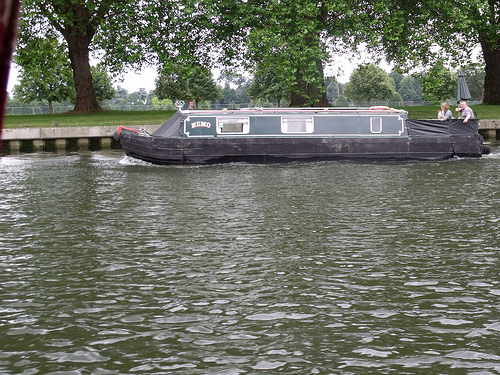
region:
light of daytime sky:
[10, 33, 484, 95]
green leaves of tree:
[345, 63, 391, 99]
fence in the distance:
[3, 101, 440, 115]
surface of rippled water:
[3, 144, 498, 372]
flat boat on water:
[115, 107, 491, 162]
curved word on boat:
[191, 120, 211, 130]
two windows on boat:
[215, 115, 314, 134]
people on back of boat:
[436, 100, 475, 125]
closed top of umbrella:
[453, 67, 470, 104]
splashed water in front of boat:
[119, 154, 154, 167]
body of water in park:
[15, 169, 490, 364]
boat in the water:
[106, 96, 491, 178]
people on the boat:
[426, 98, 478, 138]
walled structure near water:
[2, 122, 129, 146]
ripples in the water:
[353, 338, 480, 365]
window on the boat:
[218, 114, 250, 131]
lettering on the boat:
[187, 118, 214, 132]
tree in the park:
[338, 53, 403, 109]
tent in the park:
[443, 66, 476, 111]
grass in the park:
[21, 112, 152, 124]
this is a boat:
[113, 102, 438, 159]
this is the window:
[217, 119, 246, 134]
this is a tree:
[145, 14, 217, 100]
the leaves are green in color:
[174, 61, 192, 83]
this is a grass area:
[55, 110, 93, 125]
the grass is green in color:
[36, 106, 71, 123]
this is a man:
[455, 90, 480, 125]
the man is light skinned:
[458, 101, 467, 116]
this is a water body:
[149, 174, 430, 352]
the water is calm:
[282, 200, 468, 315]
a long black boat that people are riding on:
[113, 100, 490, 168]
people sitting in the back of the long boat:
[432, 94, 474, 121]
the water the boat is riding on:
[2, 149, 498, 373]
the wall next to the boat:
[4, 125, 116, 149]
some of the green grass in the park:
[10, 111, 169, 123]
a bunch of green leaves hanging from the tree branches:
[117, 4, 485, 108]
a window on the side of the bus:
[218, 118, 245, 133]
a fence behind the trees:
[4, 100, 79, 115]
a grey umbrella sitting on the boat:
[454, 70, 470, 100]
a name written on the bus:
[190, 120, 214, 133]